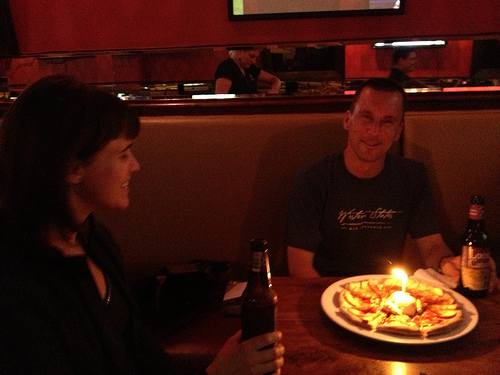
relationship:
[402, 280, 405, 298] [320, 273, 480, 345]
candle in middle of plate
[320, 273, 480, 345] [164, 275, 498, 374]
plate on table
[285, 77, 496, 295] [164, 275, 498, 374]
person sitting at table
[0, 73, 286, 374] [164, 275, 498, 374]
person sitting at table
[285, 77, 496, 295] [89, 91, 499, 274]
person sitting on booth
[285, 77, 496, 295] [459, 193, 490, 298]
person holding beer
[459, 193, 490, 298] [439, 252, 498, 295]
beer in hand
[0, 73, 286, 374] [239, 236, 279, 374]
person holding beer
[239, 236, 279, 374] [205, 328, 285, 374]
beer in hand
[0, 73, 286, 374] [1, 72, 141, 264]
person has hair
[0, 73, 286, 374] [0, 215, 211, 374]
person wearing shirt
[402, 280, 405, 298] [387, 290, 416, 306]
candle in ice cream scoop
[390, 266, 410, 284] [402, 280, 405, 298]
flame on candle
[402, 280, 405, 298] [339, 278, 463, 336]
candle in pizza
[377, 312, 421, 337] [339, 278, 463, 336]
slice of pizza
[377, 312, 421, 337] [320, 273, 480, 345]
slice on plate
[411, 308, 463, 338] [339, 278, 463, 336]
slice of pizza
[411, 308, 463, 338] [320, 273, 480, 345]
slice on plate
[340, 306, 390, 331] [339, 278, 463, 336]
slice of pizza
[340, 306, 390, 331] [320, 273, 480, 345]
slice on plate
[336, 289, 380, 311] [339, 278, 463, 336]
slice of pizza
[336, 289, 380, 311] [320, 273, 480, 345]
slice on plate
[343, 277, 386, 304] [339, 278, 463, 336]
slice of pizza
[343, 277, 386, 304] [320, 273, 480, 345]
slice on plate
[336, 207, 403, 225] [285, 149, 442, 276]
logo on tee shirt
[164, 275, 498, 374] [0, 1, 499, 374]
table in restaurant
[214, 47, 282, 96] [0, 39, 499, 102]
person in restaurant kitchen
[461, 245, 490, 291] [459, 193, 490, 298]
label on beer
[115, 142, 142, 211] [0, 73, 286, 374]
face on person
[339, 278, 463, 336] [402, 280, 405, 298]
pizza with candle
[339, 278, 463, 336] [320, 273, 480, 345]
pizza on plate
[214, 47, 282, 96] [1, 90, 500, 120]
person behind bar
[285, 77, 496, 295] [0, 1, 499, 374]
person in restaurant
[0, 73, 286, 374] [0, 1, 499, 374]
person in restaurant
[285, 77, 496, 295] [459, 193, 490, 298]
person drinking beer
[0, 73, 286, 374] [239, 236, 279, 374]
person drinking beer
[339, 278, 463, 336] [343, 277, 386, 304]
pizza cut into slice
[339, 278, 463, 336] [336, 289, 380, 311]
pizza cut into slice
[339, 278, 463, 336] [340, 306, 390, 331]
pizza cut into slice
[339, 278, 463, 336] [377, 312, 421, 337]
pizza cut into slice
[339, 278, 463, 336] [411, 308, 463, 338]
pizza cut into slice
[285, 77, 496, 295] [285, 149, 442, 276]
person wearing a tee shirt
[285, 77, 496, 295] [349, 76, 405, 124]
person has hair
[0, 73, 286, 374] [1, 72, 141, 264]
person with hair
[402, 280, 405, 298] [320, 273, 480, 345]
candle on plate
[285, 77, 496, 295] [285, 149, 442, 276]
person wearing tee shirt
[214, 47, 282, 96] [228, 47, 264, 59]
person with hair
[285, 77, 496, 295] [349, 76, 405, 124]
person with hair